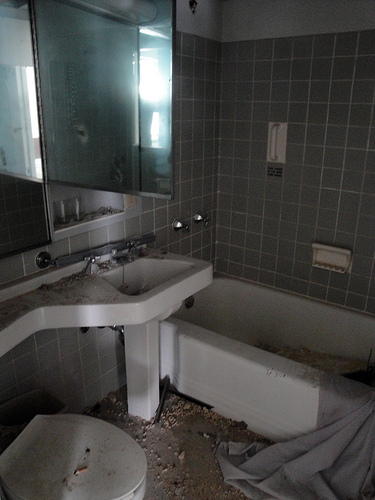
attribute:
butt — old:
[71, 462, 89, 479]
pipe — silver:
[114, 325, 125, 338]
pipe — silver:
[78, 324, 95, 338]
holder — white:
[308, 240, 358, 273]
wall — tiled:
[181, 33, 358, 301]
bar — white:
[265, 122, 280, 162]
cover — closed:
[2, 417, 145, 498]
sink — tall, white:
[72, 241, 214, 419]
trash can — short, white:
[0, 378, 76, 439]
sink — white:
[2, 235, 214, 422]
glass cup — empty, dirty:
[53, 195, 71, 225]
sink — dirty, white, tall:
[0, 238, 222, 461]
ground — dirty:
[305, 80, 355, 125]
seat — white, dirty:
[0, 402, 150, 496]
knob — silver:
[192, 210, 213, 226]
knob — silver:
[172, 217, 192, 232]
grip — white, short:
[265, 121, 291, 165]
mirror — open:
[2, 2, 179, 202]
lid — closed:
[8, 410, 149, 498]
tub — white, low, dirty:
[160, 271, 374, 446]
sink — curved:
[55, 237, 176, 319]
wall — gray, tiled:
[213, 29, 373, 318]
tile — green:
[310, 56, 333, 83]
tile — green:
[305, 101, 328, 125]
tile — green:
[300, 144, 324, 167]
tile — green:
[250, 81, 272, 102]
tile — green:
[260, 197, 283, 219]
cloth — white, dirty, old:
[282, 452, 292, 468]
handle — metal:
[173, 217, 192, 234]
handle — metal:
[192, 211, 213, 227]